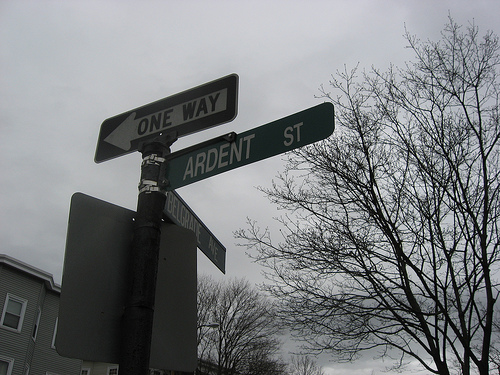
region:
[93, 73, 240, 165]
a black and white sign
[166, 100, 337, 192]
a green and white sign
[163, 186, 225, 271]
a green and white sign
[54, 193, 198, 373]
a rectangle road sign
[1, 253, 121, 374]
a gray building in the corner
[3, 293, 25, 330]
a window on the building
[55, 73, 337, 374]
a post covered in signs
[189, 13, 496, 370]
trees with no leaves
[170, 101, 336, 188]
a green street sign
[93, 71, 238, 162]
a one way street sign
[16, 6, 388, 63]
The sky is gray and cloudy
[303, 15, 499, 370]
The tree is tall with no leaves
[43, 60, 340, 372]
The street sign on the corner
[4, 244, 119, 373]
The building is gray and white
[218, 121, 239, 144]
The screw holding the sign together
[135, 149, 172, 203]
The fastener on the pole to hold the signs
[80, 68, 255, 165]
The sign says "one way"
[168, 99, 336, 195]
The sign says "Ardent St "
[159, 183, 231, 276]
The sign says "Belgrade Ave"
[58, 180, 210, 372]
The sign is turned backwards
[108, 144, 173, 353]
this is a pole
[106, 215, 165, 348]
the pole is black in color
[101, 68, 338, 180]
these are side directions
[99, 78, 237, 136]
the direction post is black in color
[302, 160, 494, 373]
this is the tree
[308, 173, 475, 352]
the tree is dry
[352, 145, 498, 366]
the tree is branchy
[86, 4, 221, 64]
the sky is grey in color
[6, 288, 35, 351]
this is a building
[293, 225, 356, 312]
the branches are wavy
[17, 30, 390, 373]
These are street signs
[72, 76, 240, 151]
This sign says One way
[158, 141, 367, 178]
This sign says Ardent St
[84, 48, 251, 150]
This sign has an arrow on it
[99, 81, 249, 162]
The sign is white and black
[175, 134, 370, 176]
The sign is green and white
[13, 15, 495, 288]
The weather is overcast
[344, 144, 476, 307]
This is a large tree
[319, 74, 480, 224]
The tree has no leaves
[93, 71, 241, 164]
black and white traffic sign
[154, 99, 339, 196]
green and white street sign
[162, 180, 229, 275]
green and white street sign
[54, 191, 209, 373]
rectangular traffic sign attached to pole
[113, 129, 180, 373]
thick metal pole with many signs on it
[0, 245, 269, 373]
light colored houses along street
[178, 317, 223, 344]
street light near houses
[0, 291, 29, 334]
rectangular window with white trim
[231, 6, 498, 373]
leafless trees near signs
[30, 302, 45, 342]
rectangular window with white trim